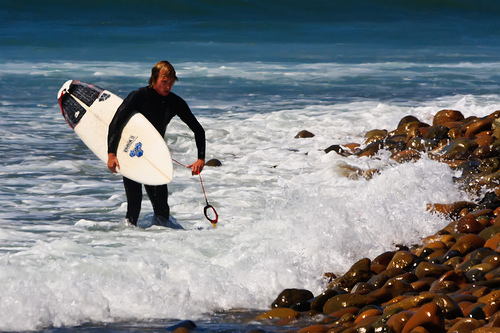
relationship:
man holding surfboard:
[107, 61, 206, 225] [58, 80, 175, 185]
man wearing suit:
[107, 61, 206, 225] [106, 88, 206, 226]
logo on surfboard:
[129, 142, 144, 158] [58, 80, 175, 185]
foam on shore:
[0, 92, 497, 332] [270, 109, 499, 332]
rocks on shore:
[257, 110, 500, 333] [270, 109, 499, 332]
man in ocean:
[107, 61, 206, 225] [0, 2, 500, 333]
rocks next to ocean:
[257, 110, 500, 333] [0, 2, 500, 333]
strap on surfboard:
[172, 158, 194, 171] [58, 80, 175, 185]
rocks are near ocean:
[257, 110, 500, 333] [0, 2, 500, 333]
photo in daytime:
[2, 1, 498, 333] [0, 2, 498, 332]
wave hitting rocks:
[0, 155, 468, 332] [257, 110, 500, 333]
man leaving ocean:
[107, 61, 206, 225] [0, 2, 500, 333]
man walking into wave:
[107, 61, 206, 225] [0, 155, 468, 332]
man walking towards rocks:
[107, 61, 206, 225] [257, 110, 500, 333]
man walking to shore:
[107, 61, 206, 225] [270, 109, 499, 332]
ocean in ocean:
[0, 2, 500, 333] [0, 2, 500, 333]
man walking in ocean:
[107, 61, 206, 225] [0, 2, 500, 333]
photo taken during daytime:
[2, 1, 498, 333] [0, 2, 498, 332]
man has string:
[107, 61, 206, 225] [199, 173, 209, 207]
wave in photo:
[0, 155, 468, 332] [2, 1, 498, 333]